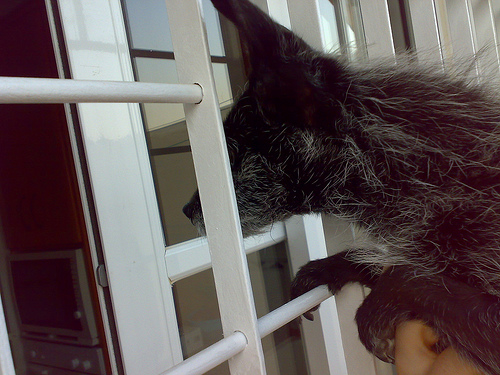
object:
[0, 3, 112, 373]
background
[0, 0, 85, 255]
cabinet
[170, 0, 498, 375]
dog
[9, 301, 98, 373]
knobs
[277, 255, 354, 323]
paw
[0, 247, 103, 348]
monitor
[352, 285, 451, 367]
paw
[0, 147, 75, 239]
wall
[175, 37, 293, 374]
posts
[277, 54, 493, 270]
hair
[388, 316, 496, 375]
hand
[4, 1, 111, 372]
kitchen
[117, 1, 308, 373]
window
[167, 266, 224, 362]
window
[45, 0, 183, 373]
white trim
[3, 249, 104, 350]
television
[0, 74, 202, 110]
bar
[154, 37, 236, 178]
bars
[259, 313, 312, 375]
window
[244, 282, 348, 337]
bar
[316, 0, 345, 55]
window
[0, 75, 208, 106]
rail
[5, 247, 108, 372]
oven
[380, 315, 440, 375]
fingers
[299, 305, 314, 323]
toenails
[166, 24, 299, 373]
board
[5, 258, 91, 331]
screen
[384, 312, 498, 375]
person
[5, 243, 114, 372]
device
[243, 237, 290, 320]
window